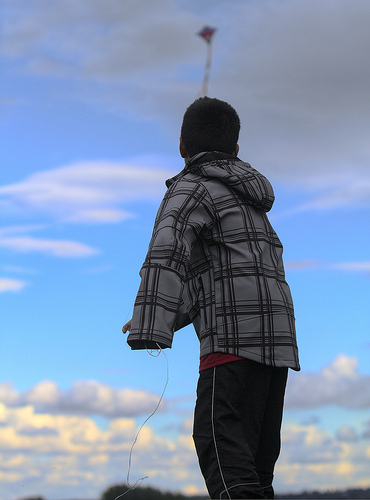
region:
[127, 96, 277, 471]
this is a boy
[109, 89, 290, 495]
the boy is looking above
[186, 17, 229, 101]
the kite is on air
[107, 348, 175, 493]
this is a rope on the boys hand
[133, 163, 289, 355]
this is a jacket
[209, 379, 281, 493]
the trousers are black in color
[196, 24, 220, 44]
the kite is red in color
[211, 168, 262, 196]
the jacket has hood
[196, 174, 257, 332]
the jacket is grey in color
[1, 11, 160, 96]
the clouds are grey in color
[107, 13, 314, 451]
person flying a kite overhead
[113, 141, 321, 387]
grey and black plaid jacket with hood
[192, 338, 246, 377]
hem of red shirt handing below jacket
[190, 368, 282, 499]
white lines down and across dark pants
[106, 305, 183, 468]
string coming out of a sleeve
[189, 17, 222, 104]
diamond kite with a tail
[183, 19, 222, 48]
red kite with blue points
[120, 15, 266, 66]
grey clouds around kite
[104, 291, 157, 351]
finger curled behind sleeve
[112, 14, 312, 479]
boy standing sideways watching kite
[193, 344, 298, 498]
pants are black with white line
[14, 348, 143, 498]
sky is blue and white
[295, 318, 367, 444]
sky is blue and white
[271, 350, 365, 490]
sky is blue and white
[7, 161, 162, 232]
the clouds are puffy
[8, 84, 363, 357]
the sky is blue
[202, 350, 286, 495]
the pants are black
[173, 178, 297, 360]
the coat is gray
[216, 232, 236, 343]
the pattern is on the jacket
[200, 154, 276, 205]
hood is on the jacket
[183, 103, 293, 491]
there is one boy shown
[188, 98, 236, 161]
the hair is black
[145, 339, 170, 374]
the string is white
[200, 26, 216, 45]
the kite is in the sky